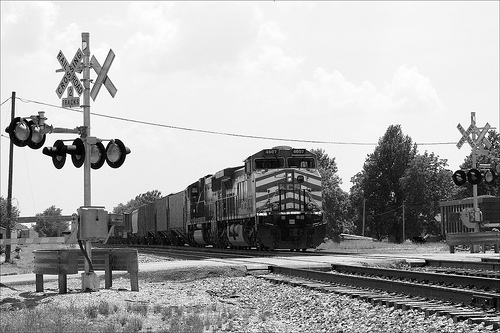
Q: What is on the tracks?
A: The train.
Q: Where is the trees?
A: To the right of the train.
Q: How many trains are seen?
A: One.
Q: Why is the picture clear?
A: Daytime.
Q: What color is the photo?
A: Black and white.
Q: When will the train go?
A: Later.